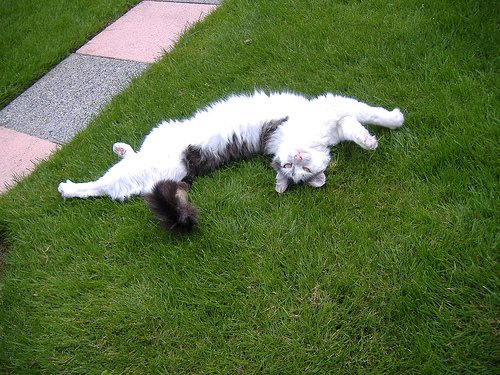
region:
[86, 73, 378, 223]
Cat is white and black color.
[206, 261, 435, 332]
grass is green color.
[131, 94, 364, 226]
Cat is lying in grass.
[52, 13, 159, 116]
Pathway is made of tiles.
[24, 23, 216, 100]
Tiles are fixed between the tiles.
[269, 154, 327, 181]
eyes are yellow color.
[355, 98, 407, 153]
Claws are white color.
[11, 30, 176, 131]
Tiles are pink and grey color.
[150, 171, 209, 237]
Tail is black color.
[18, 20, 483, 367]
Day time picture.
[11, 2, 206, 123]
Pavers in the grass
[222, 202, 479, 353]
Green grass in a lawn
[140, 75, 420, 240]
A fuzzy black and white cat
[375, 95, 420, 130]
A white cat paw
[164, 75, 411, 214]
A cat laying in the grass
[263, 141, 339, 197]
A cat's head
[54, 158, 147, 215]
A cat's back leg stretched out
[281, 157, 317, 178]
Two cat eyes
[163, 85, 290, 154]
A cat's belly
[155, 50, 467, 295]
A cat laying in a lawn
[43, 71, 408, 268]
cat lying in the grass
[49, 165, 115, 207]
back leg and paw of a cat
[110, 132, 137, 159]
paw of a cat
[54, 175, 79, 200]
paw of a cat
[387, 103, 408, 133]
paw of a cat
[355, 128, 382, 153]
paw of a cat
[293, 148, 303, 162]
pink nose of a cat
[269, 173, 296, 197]
ear of a cat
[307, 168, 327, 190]
ear of a cat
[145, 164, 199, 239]
tail of a cat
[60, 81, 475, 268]
Cat laying in the grass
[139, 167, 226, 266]
The cat has a bushy tail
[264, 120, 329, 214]
The cat is looking up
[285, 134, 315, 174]
The cats nose pink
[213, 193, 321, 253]
The grass is green and long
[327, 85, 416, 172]
The cat has white feet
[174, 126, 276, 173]
The cat has black on its back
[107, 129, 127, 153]
The cat has pink paws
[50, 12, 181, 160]
The sidewalk is different colors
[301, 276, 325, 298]
Clump of dry grass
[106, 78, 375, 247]
cat laying on grass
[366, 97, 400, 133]
white paw of cat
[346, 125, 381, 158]
white paw of cat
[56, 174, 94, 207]
white paw of cat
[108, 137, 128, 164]
white paw of cat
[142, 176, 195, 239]
tail of cat on grass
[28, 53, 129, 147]
tile on side of grass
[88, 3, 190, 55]
tile on side of grass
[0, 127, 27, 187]
tile on side of grass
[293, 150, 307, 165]
pink nose on cat